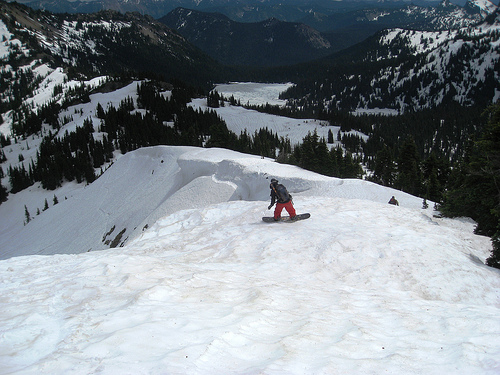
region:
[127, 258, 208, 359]
The snow is white.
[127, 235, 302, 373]
The snow is white.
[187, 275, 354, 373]
The snow is white.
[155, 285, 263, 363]
The snow is white.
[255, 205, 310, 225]
a snowboard on the snow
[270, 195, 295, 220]
red pants on a skier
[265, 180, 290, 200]
a grey coat on a skier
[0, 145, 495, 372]
a snowy white slope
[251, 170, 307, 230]
a snowboarder on a board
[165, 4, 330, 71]
a green mountain in the distance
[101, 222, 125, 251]
rock showing through snow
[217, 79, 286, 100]
a snowy white valley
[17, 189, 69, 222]
a thin line of pine trees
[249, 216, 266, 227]
the shadow of a snowboarder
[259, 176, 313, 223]
a snow boarder on mountain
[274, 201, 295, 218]
red ski pants on man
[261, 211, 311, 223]
a long snow board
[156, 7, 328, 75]
a mountain in the background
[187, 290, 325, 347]
snow on top of mountain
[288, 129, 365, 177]
a group of pine trees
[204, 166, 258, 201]
a trail in the snow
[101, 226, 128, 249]
rocks showing through snow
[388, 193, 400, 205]
a snow boarder in the distance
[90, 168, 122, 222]
a long trail in the snow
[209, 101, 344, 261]
Skier on the mountain.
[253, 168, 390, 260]
Snowboarder on the mountain.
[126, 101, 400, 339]
Snow on the mountain.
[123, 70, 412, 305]
Trees in the background.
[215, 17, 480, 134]
Snow on the background mountains.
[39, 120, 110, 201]
Pine trees on the mountain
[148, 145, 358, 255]
Collapsed part of the snow.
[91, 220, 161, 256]
Grass through the snow.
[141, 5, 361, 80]
Mountain in the distance.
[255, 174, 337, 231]
Snowboarded with red pants.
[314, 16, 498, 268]
Snowy Evergreen covered mountainside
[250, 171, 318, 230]
Man snowboarding down mountain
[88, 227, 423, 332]
snow with brown streaks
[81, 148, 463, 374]
Snow covered mountainside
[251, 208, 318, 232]
Dark colored snowboard being used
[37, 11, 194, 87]
Mountain slope with melting ice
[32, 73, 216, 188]
Many tall Evergreen trees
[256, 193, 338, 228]
Bright red snowboarding pants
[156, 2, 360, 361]
Steep mountainside ski slope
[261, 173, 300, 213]
Grey snowboarding jacket